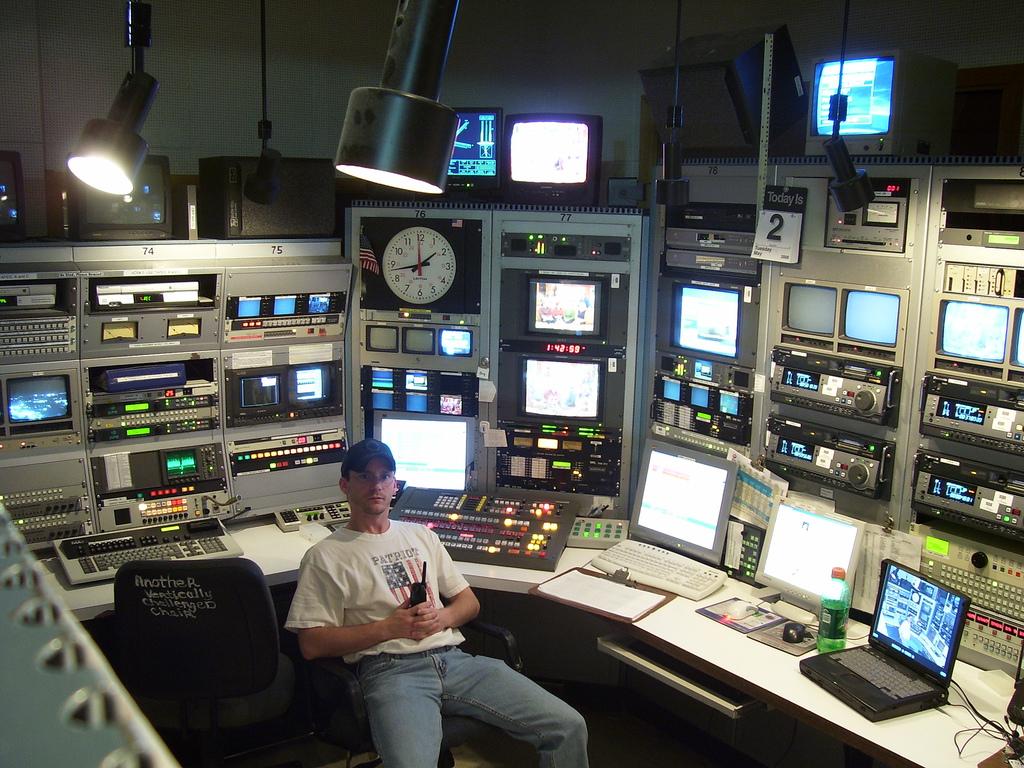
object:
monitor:
[935, 297, 1011, 365]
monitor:
[851, 299, 898, 345]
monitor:
[778, 284, 832, 367]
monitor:
[866, 558, 972, 676]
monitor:
[755, 501, 846, 606]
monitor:
[663, 284, 746, 361]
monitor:
[523, 271, 610, 335]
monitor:
[515, 349, 602, 420]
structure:
[515, 143, 688, 419]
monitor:
[378, 419, 465, 501]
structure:
[378, 210, 487, 501]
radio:
[397, 549, 436, 603]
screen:
[11, 360, 88, 427]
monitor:
[6, 364, 72, 431]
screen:
[862, 553, 972, 689]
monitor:
[859, 557, 974, 676]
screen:
[621, 437, 738, 571]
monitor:
[621, 437, 738, 571]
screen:
[501, 99, 618, 202]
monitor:
[501, 111, 604, 202]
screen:
[221, 282, 352, 346]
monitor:
[221, 282, 352, 346]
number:
[751, 184, 812, 277]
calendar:
[738, 184, 813, 271]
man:
[283, 441, 587, 767]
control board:
[375, 481, 590, 570]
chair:
[90, 542, 297, 767]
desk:
[39, 494, 396, 627]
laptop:
[792, 555, 972, 725]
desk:
[560, 468, 1022, 767]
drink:
[809, 562, 858, 666]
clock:
[373, 226, 472, 310]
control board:
[329, 180, 505, 520]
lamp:
[329, 0, 472, 200]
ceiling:
[155, 5, 335, 150]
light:
[56, 66, 165, 199]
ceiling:
[14, 0, 1005, 53]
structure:
[20, 130, 1024, 661]